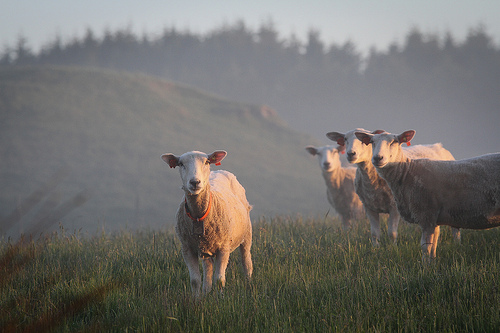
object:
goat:
[160, 150, 254, 305]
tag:
[215, 161, 222, 166]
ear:
[207, 150, 227, 165]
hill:
[1, 62, 342, 240]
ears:
[160, 152, 185, 166]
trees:
[3, 12, 498, 106]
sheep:
[303, 143, 343, 231]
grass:
[0, 190, 500, 330]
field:
[1, 16, 498, 330]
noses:
[372, 155, 384, 162]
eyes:
[390, 139, 398, 145]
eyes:
[369, 140, 374, 143]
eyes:
[333, 150, 337, 154]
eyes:
[205, 160, 210, 166]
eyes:
[178, 162, 184, 166]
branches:
[6, 218, 171, 328]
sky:
[293, 14, 401, 57]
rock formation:
[205, 86, 292, 153]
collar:
[183, 188, 212, 221]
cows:
[330, 129, 401, 262]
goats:
[360, 129, 499, 254]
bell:
[196, 217, 200, 223]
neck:
[181, 192, 208, 217]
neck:
[383, 154, 419, 191]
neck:
[353, 160, 375, 181]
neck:
[323, 166, 345, 189]